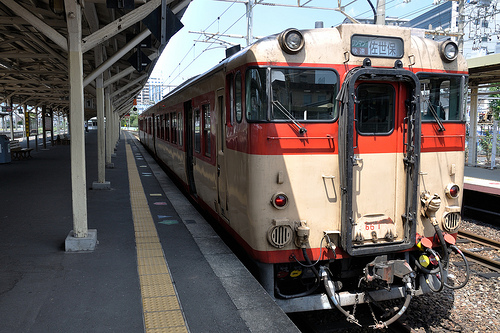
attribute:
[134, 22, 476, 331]
train — parked, peach, striped, red, dirty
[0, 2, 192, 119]
cover — hanging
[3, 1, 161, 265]
supports — standing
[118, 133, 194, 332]
line — yellow, bumpy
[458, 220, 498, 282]
tracks — empty, old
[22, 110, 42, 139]
sign — colored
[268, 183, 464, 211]
lights — red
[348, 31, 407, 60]
letters — chinese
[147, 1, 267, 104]
wires — hanging, black, electrical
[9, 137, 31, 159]
bench — sitting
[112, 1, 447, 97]
sky — bright, blue, clear, sunny